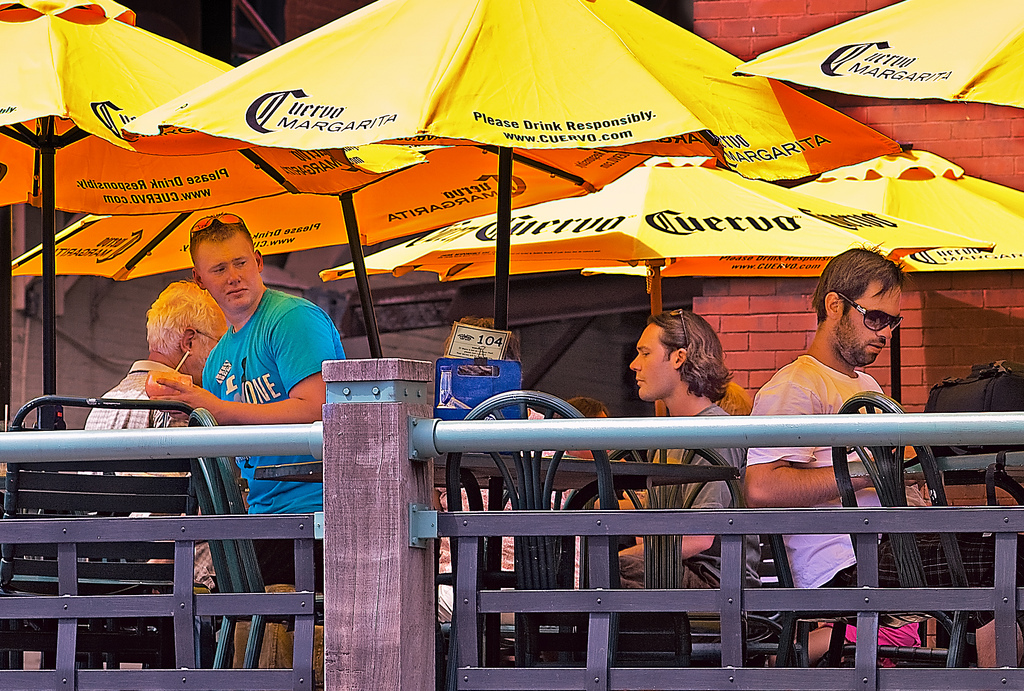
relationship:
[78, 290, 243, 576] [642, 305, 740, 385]
man with hair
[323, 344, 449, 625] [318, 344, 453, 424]
post with metal pieces